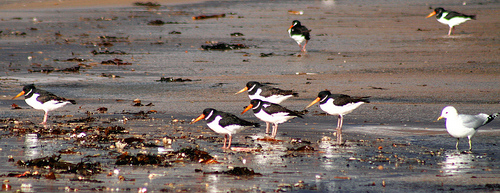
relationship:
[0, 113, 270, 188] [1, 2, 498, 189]
debris on ground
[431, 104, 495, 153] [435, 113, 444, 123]
bird has beak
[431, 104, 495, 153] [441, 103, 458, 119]
bird has head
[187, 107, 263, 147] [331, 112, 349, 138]
bird has legs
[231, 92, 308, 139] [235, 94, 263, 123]
bird has beak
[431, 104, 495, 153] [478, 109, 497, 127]
bird has tail feathers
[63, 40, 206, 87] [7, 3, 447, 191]
debris on beach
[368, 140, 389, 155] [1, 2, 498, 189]
orange object on ground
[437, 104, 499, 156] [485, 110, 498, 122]
bird with black tail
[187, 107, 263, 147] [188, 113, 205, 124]
bird has beaks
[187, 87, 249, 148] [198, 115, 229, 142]
bird has breast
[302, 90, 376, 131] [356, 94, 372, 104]
bird has black tail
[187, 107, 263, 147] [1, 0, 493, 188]
bird on ground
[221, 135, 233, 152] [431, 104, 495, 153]
two feet on bird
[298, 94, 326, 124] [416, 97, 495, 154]
bill of bird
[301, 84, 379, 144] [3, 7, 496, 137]
bird on beach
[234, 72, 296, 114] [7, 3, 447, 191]
bird on beach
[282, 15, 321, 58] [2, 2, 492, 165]
bird on beach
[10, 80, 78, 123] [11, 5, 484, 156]
bird standing in group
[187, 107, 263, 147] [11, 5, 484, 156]
bird standing in group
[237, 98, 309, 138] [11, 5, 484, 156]
bird standing in group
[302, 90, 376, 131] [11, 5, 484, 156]
bird standing in group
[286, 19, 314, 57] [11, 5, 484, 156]
bird standing in group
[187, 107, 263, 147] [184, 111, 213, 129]
bird have beaks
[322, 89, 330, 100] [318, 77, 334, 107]
stripe on throat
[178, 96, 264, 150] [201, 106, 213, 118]
streak on head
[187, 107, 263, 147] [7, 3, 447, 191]
bird on beach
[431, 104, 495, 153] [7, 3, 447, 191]
bird on beach